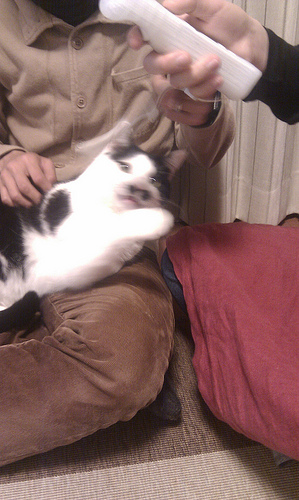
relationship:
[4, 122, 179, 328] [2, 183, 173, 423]
cat on lap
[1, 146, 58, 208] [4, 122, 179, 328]
hand on cat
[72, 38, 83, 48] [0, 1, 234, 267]
button on shirt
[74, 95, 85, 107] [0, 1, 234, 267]
button on shirt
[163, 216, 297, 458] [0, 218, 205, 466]
shirt on lap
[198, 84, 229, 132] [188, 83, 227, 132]
watch on wrist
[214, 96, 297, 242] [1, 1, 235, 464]
curtain behind person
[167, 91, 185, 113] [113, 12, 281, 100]
ring on hand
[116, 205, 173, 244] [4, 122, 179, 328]
paw on cat